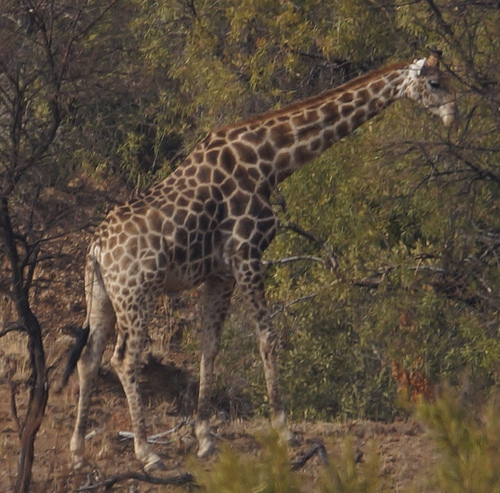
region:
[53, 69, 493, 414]
the giraffe has spots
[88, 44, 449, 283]
the giraffe has spots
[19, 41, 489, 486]
an out of focus photoghraph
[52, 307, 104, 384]
a long black tail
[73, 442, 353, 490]
a broken tree branch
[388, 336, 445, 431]
a few dead leaves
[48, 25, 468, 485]
a giraffe in the wild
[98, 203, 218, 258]
brown and white fur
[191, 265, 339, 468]
a pair of long legs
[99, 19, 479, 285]
a leafy tree in background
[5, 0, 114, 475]
a dead brown tree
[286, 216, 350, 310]
a few tree branches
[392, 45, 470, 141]
head of a giraffe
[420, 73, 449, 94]
eye of a giraffe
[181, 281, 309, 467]
front legs of a giraffe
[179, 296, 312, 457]
long front legs of a giraffe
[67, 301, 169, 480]
rear legs of giraffe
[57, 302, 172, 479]
long rear legs of giraffe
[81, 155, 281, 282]
body of a giraffe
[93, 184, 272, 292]
big body of giraffe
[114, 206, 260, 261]
spots on a giraffe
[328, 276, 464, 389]
set of healthy trees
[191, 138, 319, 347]
A giraffe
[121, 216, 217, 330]
A giraffe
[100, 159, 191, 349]
A giraffe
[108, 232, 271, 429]
A giraffe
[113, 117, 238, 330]
A giraffe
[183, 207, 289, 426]
A giraffe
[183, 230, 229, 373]
A giraffe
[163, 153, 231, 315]
A giraffe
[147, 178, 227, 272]
A giraffe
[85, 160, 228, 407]
A giraffe